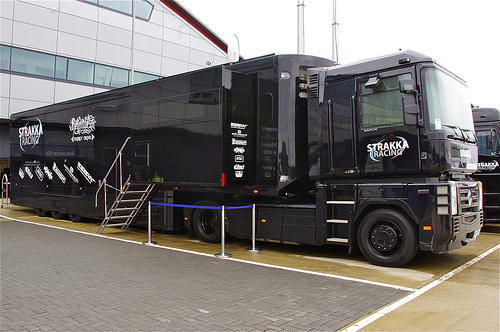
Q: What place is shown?
A: It is a parking lot.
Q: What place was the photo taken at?
A: It was taken at the parking lot.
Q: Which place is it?
A: It is a parking lot.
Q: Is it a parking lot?
A: Yes, it is a parking lot.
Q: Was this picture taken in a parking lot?
A: Yes, it was taken in a parking lot.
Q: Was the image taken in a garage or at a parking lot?
A: It was taken at a parking lot.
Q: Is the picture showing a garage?
A: No, the picture is showing a parking lot.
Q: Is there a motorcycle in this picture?
A: No, there are no motorcycles.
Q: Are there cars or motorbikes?
A: No, there are no motorbikes or cars.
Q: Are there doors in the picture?
A: Yes, there is a door.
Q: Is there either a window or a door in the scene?
A: Yes, there is a door.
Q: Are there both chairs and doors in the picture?
A: No, there is a door but no chairs.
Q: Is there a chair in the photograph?
A: No, there are no chairs.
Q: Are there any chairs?
A: No, there are no chairs.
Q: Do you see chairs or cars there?
A: No, there are no chairs or cars.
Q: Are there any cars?
A: No, there are no cars.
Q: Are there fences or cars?
A: No, there are no cars or fences.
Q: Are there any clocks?
A: No, there are no clocks.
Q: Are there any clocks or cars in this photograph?
A: No, there are no clocks or cars.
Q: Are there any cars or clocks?
A: No, there are no clocks or cars.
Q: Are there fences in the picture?
A: No, there are no fences.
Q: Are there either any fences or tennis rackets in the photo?
A: No, there are no fences or tennis rackets.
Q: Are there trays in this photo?
A: No, there are no trays.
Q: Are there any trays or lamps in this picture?
A: No, there are no trays or lamps.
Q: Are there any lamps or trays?
A: No, there are no trays or lamps.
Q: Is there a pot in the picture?
A: No, there are no pots.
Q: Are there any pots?
A: No, there are no pots.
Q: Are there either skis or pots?
A: No, there are no pots or skis.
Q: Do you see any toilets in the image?
A: No, there are no toilets.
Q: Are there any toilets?
A: No, there are no toilets.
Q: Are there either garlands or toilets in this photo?
A: No, there are no toilets or garlands.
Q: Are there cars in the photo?
A: No, there are no cars.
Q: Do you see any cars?
A: No, there are no cars.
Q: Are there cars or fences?
A: No, there are no cars or fences.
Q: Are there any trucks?
A: Yes, there is a truck.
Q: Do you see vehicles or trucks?
A: Yes, there is a truck.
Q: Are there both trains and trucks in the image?
A: No, there is a truck but no trains.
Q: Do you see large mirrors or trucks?
A: Yes, there is a large truck.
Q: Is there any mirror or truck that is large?
A: Yes, the truck is large.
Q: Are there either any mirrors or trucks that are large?
A: Yes, the truck is large.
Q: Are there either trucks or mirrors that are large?
A: Yes, the truck is large.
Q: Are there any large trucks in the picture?
A: Yes, there is a large truck.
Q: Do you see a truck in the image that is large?
A: Yes, there is a truck that is large.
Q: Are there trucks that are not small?
A: Yes, there is a large truck.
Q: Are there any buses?
A: No, there are no buses.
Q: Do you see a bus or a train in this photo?
A: No, there are no buses or trains.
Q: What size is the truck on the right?
A: The truck is large.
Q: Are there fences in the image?
A: No, there are no fences.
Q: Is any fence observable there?
A: No, there are no fences.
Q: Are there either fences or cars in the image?
A: No, there are no fences or cars.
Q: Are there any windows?
A: Yes, there is a window.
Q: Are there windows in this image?
A: Yes, there is a window.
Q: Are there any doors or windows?
A: Yes, there is a window.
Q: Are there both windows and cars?
A: No, there is a window but no cars.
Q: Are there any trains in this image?
A: No, there are no trains.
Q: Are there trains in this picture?
A: No, there are no trains.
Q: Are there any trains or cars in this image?
A: No, there are no trains or cars.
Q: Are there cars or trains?
A: No, there are no trains or cars.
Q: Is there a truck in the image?
A: Yes, there is a truck.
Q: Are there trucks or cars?
A: Yes, there is a truck.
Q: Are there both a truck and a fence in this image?
A: No, there is a truck but no fences.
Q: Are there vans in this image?
A: No, there are no vans.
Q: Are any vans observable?
A: No, there are no vans.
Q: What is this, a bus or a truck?
A: This is a truck.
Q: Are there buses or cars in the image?
A: No, there are no buses or cars.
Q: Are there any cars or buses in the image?
A: No, there are no buses or cars.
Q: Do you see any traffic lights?
A: No, there are no traffic lights.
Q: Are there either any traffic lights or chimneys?
A: No, there are no traffic lights or chimneys.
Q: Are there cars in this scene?
A: No, there are no cars.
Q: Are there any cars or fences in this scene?
A: No, there are no cars or fences.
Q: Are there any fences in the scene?
A: No, there are no fences.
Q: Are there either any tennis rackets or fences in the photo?
A: No, there are no fences or tennis rackets.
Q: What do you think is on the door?
A: The logo is on the door.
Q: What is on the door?
A: The logo is on the door.